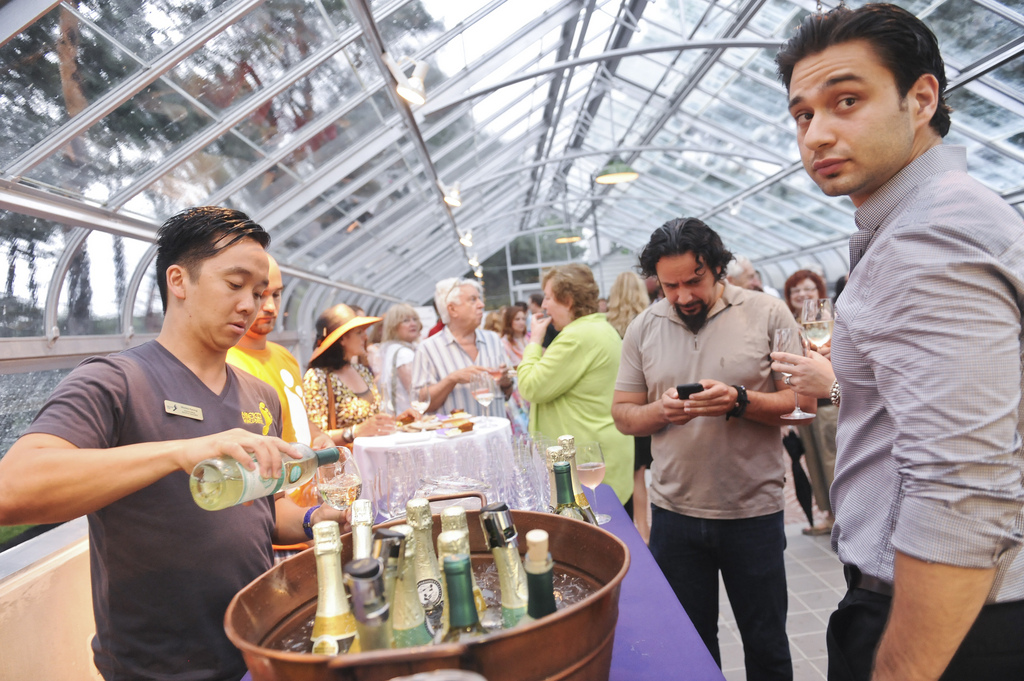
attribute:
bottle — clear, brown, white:
[191, 424, 355, 513]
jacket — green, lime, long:
[522, 310, 637, 481]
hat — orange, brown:
[307, 300, 380, 356]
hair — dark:
[160, 201, 267, 274]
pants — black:
[640, 508, 803, 677]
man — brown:
[17, 184, 327, 676]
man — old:
[419, 266, 524, 441]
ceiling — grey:
[14, 4, 1023, 329]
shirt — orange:
[224, 336, 321, 467]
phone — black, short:
[676, 377, 708, 406]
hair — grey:
[380, 298, 413, 335]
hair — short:
[545, 259, 603, 317]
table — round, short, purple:
[343, 397, 526, 508]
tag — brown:
[157, 391, 211, 427]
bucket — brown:
[218, 506, 637, 679]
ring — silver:
[781, 372, 799, 388]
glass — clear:
[313, 452, 366, 505]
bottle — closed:
[431, 528, 485, 650]